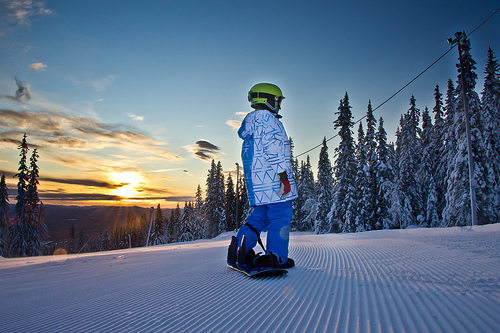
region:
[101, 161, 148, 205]
A glowing sun setting in the sky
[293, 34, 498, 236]
A group of trees covered in snow.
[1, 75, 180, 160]
Wispy clouds in the sky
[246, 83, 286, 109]
A yellow helmet on a head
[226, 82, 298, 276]
A snowboarder stepping off their snowboard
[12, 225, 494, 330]
Directional pattern in the snow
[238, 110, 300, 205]
A person wearing a white coat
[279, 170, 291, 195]
A red glove on a hand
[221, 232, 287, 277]
A snowboard on the ground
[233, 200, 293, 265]
Light blue pants being worn.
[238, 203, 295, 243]
the pants are blue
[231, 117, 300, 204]
the jacket is white and blue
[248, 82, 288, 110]
the helmet is green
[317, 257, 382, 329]
skitrucks are on the snow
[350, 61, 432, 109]
the wire is above the ground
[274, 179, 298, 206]
the glove is red and white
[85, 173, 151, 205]
the sun is setting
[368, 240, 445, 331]
the snow is white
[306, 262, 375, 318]
shadow is on the ground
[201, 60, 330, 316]
this is a person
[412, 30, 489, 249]
a tree covered in snow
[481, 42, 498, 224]
a tree covered in snow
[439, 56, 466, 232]
a tree covered in snow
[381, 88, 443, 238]
a tree covered in snow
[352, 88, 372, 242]
a tree covered in snow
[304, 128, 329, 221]
a tree covered in snow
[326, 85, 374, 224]
a tree covered in snow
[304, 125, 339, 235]
a tree covered in snow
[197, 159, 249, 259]
a tree covered in snow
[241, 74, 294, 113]
face of the person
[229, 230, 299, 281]
shoe of the boy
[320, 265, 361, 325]
lines on the ground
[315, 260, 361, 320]
lines on the snow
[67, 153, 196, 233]
a sun in the sky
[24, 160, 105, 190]
clouds in the sky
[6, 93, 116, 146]
white group of clouds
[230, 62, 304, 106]
a man wearing helmet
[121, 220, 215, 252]
shine falling on snow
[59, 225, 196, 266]
sun rays on the snow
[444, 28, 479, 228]
A tall light post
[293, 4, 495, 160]
a large hanging cable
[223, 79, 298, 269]
A person on a snowboard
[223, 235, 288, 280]
a snowboard on the ground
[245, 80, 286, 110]
A yellow helmet on a person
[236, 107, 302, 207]
a large white and blue jacket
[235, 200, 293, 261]
A pair of blue pants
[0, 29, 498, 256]
A large wooded area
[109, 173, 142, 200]
the sun in the sky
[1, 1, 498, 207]
a clear, blue sky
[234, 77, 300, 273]
a person is standing up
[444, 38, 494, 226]
a tree in a field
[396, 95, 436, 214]
a tree in the woods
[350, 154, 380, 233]
a tree in the woods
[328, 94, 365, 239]
a tree in the woods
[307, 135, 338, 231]
a tree in the woods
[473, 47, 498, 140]
a tree in the woods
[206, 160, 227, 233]
a tree in the woods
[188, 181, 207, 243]
a tree in the woods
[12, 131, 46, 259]
a tree in the woods